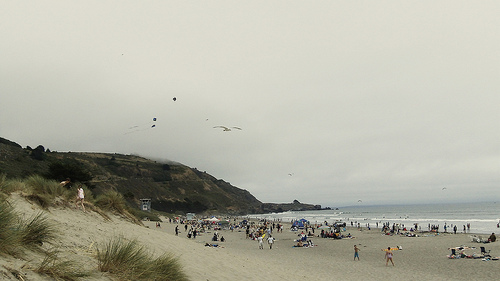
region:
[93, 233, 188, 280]
Small patch of grass in the samd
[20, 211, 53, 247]
Small patch of grass in the samd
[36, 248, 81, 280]
Small patch of grass in the samd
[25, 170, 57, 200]
Small patch of grass in the samd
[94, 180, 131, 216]
Small patch of grass in the samd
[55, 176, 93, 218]
People climbing up a hill of sand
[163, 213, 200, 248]
People standing on a beach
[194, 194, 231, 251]
People standing on a beach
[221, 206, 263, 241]
People standing on a beach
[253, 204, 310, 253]
People standing on a beach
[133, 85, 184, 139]
kites in the sky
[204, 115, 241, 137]
a bird in the sky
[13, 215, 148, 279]
grass in the sand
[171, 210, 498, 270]
people on the beach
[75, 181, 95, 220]
a person walking up the hill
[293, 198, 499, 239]
the water of the ocean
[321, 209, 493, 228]
a wave in the water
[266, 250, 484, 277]
the sand on the beach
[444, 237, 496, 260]
people laying on the beach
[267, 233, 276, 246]
a person wearing a white shirt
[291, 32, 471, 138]
A grey over cast day.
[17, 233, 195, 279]
Sea grass lines the dune.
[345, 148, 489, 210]
Some low clouds in the sky.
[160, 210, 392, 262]
Many people on the beach.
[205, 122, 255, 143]
A lone seagull take flight.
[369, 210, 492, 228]
Small wave come ashore.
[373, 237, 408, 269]
A person walking on the beach.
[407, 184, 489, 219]
Where the sky and ocean meet.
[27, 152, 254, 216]
A large hill near the beach.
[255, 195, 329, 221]
Large rock formation juts into the ocean.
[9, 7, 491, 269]
Image taken at the beach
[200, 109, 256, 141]
A large seabird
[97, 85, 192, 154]
A few kites in the sky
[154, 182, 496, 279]
The beach is full of people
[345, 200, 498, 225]
The ocean water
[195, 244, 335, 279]
Beach covered in sand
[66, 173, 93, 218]
Person walking on the hillside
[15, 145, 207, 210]
Hill covered in greenery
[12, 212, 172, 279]
Patches of long grass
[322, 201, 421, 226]
A number of people in the ocean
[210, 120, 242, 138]
a large flying seagull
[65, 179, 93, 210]
a person in a white shirt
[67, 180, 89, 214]
a person climbing up a sand dune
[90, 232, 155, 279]
a large tuft of grass growing in the sand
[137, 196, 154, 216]
a lifeguard tower in the distance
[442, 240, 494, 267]
two people lying on towels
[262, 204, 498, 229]
a wave moving towards the beach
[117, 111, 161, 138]
two kites flying in the sky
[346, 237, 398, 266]
two little boys playing together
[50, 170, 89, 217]
two children climbing a sandy hill